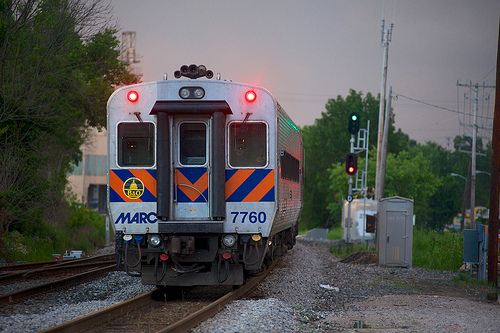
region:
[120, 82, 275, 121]
the lights are red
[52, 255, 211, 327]
the rail road is brown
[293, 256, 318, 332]
there is gravel on th eground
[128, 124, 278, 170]
the train has two windows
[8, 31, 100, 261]
there are trees on the side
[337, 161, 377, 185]
the stoplight is red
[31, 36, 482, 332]
the photo was taken during the day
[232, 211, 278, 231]
the nummber 7760 is on the train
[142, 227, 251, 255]
there are two bulbs below the train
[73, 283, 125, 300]
there is gravel between the tracks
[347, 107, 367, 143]
a bright green light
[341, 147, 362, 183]
a red traffic light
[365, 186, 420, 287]
a small grey shack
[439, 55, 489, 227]
a few telephone posts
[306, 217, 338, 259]
a straigh train track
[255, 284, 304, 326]
some piles of gravel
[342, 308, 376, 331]
a small puddle of water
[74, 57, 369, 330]
a train in motion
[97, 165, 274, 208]
blue and orange stripes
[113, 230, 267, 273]
a bunch of wires and plugs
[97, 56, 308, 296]
a white train with blue and orange stripes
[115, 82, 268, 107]
bright red lights on the back of a train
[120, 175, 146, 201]
a yellow and blue logo sticker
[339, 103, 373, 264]
green and red stoplights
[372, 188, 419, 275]
a small grey outbuilding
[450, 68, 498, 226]
a tall electrical pole with powerlines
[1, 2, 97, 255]
green dense trees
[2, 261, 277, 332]
brown train tracks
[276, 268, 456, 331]
rough rocky ground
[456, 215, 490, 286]
a blue metal pipe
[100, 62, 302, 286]
train car on a track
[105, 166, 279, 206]
orange and blue stripes on back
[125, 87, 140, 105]
red light on the left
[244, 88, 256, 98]
red light on the right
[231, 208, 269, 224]
7760 on back of train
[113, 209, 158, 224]
MARC on back of train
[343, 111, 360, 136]
green traffic light on right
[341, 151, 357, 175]
red traffic light on right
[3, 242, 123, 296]
track on the left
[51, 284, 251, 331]
track the train is on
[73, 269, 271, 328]
the tracks are rusted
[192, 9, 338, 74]
the sky is clear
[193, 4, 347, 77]
the sky is dim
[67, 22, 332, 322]
the train is stopped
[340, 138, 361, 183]
the light is red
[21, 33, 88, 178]
the tree is green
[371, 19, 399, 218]
the pole is white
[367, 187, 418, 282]
the portable is standing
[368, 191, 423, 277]
the door is white